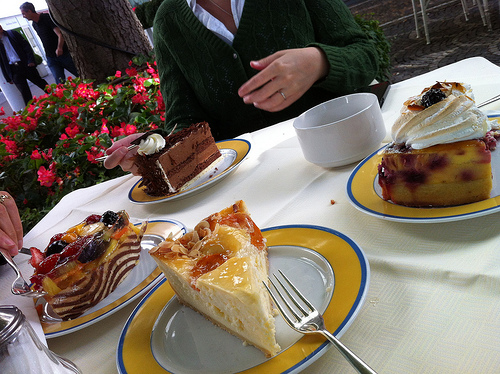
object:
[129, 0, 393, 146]
person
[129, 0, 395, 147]
green shirt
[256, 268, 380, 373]
fork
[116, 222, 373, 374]
plate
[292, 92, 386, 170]
coffee cup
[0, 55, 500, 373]
table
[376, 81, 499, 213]
fruit cake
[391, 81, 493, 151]
topping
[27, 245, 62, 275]
strawberry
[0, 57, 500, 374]
tablecloth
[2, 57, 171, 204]
red flowers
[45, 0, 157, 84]
tree trunk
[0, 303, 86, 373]
container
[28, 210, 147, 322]
dessert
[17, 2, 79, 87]
man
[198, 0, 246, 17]
silver necklace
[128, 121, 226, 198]
pie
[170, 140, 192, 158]
caramel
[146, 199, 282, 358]
cheesecake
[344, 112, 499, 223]
plate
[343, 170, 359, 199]
blue trim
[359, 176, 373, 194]
yellow trim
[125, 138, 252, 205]
plate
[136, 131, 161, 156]
icing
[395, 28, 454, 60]
stones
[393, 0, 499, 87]
ground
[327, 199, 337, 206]
crumb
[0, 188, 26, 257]
hand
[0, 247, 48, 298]
fork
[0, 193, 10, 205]
ring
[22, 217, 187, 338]
plate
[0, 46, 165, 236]
bush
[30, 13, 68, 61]
black shirt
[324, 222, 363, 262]
blue trim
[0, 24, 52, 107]
person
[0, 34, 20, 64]
white shirt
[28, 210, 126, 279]
fruit